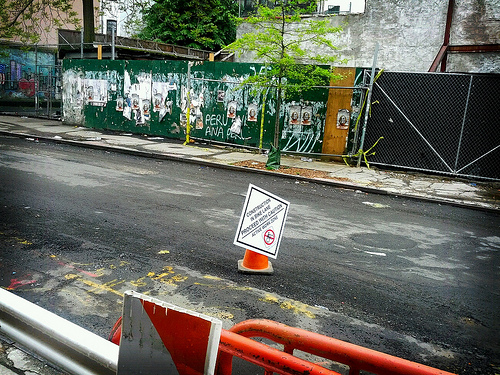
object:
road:
[0, 131, 499, 373]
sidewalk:
[1, 110, 498, 213]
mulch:
[263, 143, 284, 173]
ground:
[471, 126, 485, 138]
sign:
[121, 294, 222, 375]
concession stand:
[358, 72, 487, 160]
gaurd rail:
[0, 284, 128, 371]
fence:
[373, 68, 496, 182]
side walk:
[18, 95, 498, 212]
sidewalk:
[356, 157, 452, 217]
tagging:
[203, 111, 253, 141]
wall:
[91, 73, 147, 117]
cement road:
[0, 133, 499, 373]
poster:
[84, 82, 95, 100]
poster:
[131, 100, 140, 110]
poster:
[187, 107, 206, 132]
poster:
[289, 111, 300, 125]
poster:
[302, 111, 311, 126]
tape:
[349, 89, 370, 133]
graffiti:
[0, 23, 62, 113]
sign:
[220, 183, 290, 262]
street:
[100, 163, 184, 255]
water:
[441, 248, 465, 320]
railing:
[1, 286, 118, 371]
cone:
[236, 248, 275, 276]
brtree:
[219, 0, 354, 170]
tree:
[222, 3, 348, 192]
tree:
[139, 1, 241, 50]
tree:
[1, 1, 84, 85]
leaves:
[193, 2, 382, 106]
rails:
[215, 306, 396, 374]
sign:
[209, 182, 274, 257]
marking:
[19, 236, 164, 291]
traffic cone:
[231, 181, 294, 276]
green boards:
[47, 52, 328, 152]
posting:
[263, 228, 276, 245]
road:
[3, 134, 354, 373]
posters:
[333, 111, 353, 131]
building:
[0, 0, 105, 103]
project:
[8, 185, 479, 369]